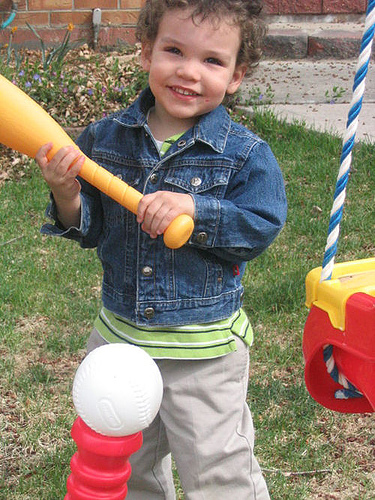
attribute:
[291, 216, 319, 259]
grass — green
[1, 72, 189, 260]
bat — plastic, yellow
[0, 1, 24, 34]
water hose — part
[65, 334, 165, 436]
baseball — white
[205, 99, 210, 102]
mark — red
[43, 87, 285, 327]
jacket — jean, blue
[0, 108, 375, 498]
grass — green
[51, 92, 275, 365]
shirt — green, white, black, striped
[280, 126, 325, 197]
grass — green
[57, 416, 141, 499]
toy — plastic, red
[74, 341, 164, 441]
ball — big, white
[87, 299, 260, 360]
shirt — green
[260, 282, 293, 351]
grass ground — green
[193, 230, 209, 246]
button — round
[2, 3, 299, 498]
child — showing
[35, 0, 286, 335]
child — happy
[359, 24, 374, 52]
line — blue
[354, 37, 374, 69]
line — blue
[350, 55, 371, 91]
line — blue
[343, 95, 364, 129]
line — blue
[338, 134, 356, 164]
line — blue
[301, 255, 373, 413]
swing — hanging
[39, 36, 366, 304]
ground — patchy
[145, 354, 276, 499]
pants — khaki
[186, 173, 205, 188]
button — silver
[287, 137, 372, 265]
grass — green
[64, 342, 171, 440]
ball — white